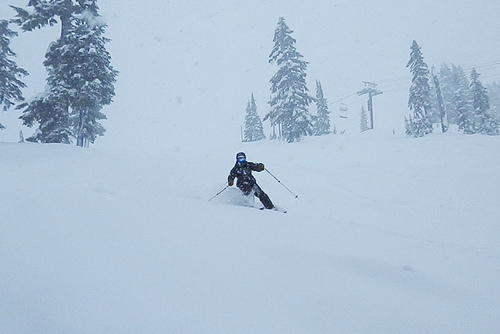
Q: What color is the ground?
A: White.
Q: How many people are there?
A: 1.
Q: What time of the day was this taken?
A: Daytime.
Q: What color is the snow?
A: White.